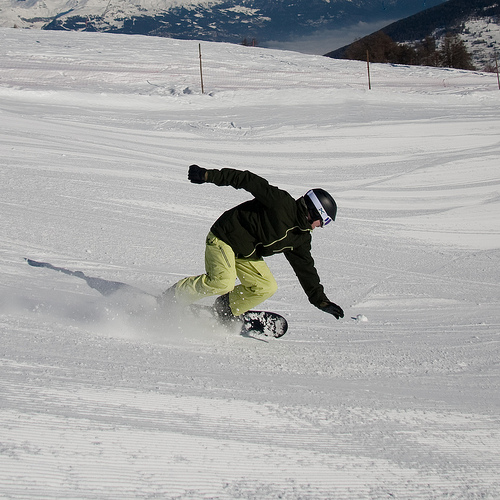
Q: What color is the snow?
A: White.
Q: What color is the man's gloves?
A: Black.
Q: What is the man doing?
A: Snowboarding.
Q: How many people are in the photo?
A: One.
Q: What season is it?
A: Winter.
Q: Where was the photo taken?
A: Mountain region.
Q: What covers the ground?
A: Snow.